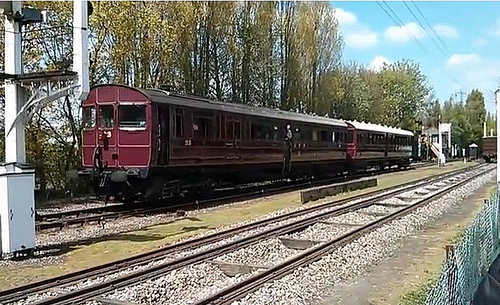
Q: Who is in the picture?
A: Nobody.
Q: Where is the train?
A: On the tracks.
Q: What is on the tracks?
A: The train.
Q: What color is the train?
A: Red.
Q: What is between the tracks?
A: Pebbles.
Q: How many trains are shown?
A: One.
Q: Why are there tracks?
A: So the train can travel.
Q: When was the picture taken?
A: Daytime.